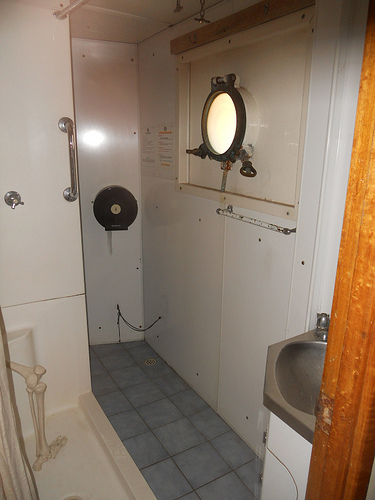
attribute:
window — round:
[180, 70, 276, 184]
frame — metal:
[185, 52, 261, 225]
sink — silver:
[261, 305, 348, 452]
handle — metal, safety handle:
[57, 116, 78, 202]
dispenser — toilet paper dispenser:
[85, 173, 162, 267]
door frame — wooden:
[359, 136, 371, 176]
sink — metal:
[258, 339, 280, 412]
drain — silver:
[124, 355, 184, 374]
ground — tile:
[84, 337, 269, 497]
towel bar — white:
[210, 200, 312, 256]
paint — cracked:
[213, 208, 288, 235]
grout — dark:
[89, 337, 261, 497]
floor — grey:
[91, 332, 264, 498]